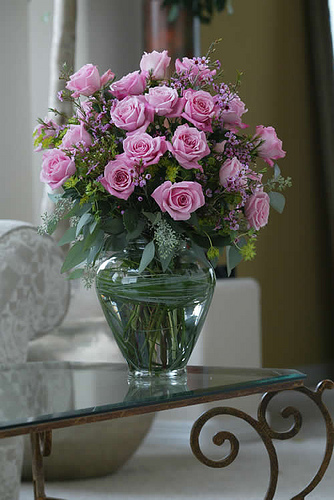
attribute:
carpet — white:
[20, 388, 333, 498]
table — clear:
[3, 359, 332, 472]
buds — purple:
[183, 115, 209, 128]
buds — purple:
[185, 89, 190, 114]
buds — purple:
[192, 87, 208, 95]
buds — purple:
[203, 110, 215, 123]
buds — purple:
[195, 108, 204, 114]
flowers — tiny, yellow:
[233, 233, 258, 262]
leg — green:
[189, 377, 333, 497]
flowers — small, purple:
[216, 130, 252, 166]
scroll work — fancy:
[184, 377, 332, 480]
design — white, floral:
[0, 221, 72, 341]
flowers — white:
[32, 45, 296, 261]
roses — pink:
[27, 39, 291, 244]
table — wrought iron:
[2, 340, 329, 438]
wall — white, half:
[203, 278, 318, 357]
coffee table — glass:
[12, 330, 317, 431]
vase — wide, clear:
[122, 252, 220, 388]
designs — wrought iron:
[178, 388, 328, 467]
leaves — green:
[209, 195, 229, 215]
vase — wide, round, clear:
[93, 238, 216, 377]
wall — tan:
[229, 0, 332, 217]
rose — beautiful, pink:
[151, 177, 214, 222]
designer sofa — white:
[1, 214, 77, 498]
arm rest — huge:
[1, 212, 77, 347]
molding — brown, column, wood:
[138, 6, 240, 277]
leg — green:
[27, 426, 55, 498]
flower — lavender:
[158, 120, 216, 178]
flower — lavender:
[143, 174, 209, 226]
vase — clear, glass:
[88, 233, 221, 380]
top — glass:
[1, 354, 311, 443]